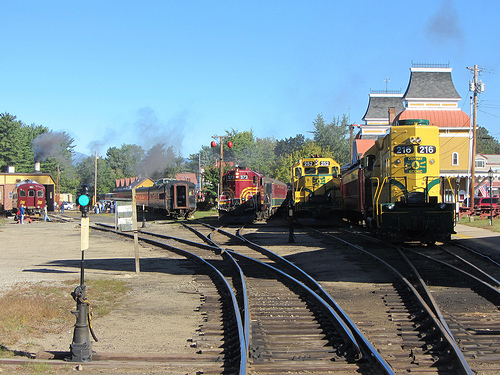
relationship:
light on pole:
[219, 135, 226, 207] [209, 140, 233, 148]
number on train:
[393, 144, 439, 157] [343, 117, 457, 247]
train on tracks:
[288, 153, 348, 225] [34, 212, 499, 374]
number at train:
[393, 144, 439, 157] [343, 117, 457, 247]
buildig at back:
[351, 62, 499, 221] [339, 63, 499, 232]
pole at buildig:
[464, 63, 490, 218] [351, 62, 499, 221]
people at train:
[19, 204, 28, 223] [14, 180, 47, 223]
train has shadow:
[343, 117, 457, 247] [227, 227, 499, 288]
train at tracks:
[288, 153, 348, 225] [34, 212, 499, 374]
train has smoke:
[14, 180, 47, 223] [31, 109, 188, 183]